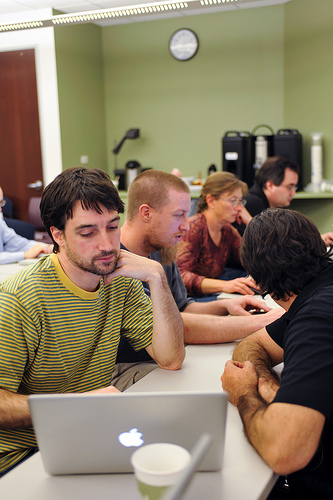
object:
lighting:
[0, 0, 269, 35]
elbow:
[266, 461, 301, 475]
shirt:
[0, 251, 153, 475]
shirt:
[115, 243, 193, 366]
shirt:
[175, 213, 242, 294]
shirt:
[265, 269, 333, 499]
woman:
[175, 171, 261, 297]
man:
[120, 170, 281, 347]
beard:
[160, 244, 177, 263]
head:
[127, 169, 190, 247]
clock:
[169, 28, 198, 60]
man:
[0, 166, 186, 479]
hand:
[104, 249, 158, 282]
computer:
[27, 394, 229, 477]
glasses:
[216, 197, 246, 207]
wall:
[104, 3, 286, 174]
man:
[221, 207, 332, 499]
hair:
[254, 350, 279, 385]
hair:
[238, 392, 269, 441]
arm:
[237, 311, 288, 394]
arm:
[238, 400, 330, 478]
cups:
[310, 131, 322, 186]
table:
[1, 299, 333, 500]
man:
[242, 156, 299, 217]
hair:
[257, 156, 299, 187]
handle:
[28, 180, 42, 190]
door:
[0, 47, 43, 222]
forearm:
[235, 393, 275, 459]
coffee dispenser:
[273, 129, 302, 192]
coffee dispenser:
[222, 131, 255, 187]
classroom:
[0, 0, 333, 499]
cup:
[129, 443, 189, 499]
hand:
[225, 278, 262, 295]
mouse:
[232, 285, 262, 296]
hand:
[234, 205, 248, 224]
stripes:
[46, 317, 88, 323]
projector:
[112, 127, 152, 191]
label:
[118, 428, 144, 447]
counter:
[121, 184, 333, 202]